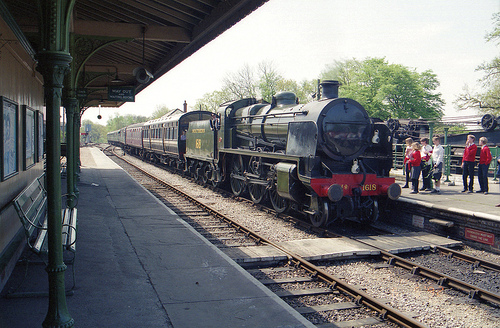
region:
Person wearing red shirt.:
[478, 141, 487, 176]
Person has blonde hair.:
[476, 128, 491, 155]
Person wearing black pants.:
[475, 163, 489, 184]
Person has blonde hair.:
[466, 130, 471, 141]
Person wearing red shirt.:
[462, 145, 472, 163]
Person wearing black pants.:
[461, 159, 473, 186]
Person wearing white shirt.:
[428, 140, 450, 169]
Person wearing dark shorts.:
[433, 160, 438, 175]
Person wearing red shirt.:
[404, 149, 419, 168]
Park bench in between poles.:
[18, 168, 80, 248]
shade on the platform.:
[119, 241, 144, 303]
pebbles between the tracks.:
[398, 278, 413, 306]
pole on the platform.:
[42, 275, 71, 320]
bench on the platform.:
[30, 192, 45, 243]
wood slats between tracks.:
[279, 276, 311, 296]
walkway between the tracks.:
[303, 240, 348, 270]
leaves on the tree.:
[392, 71, 415, 91]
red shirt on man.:
[462, 147, 475, 162]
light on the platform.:
[132, 65, 158, 90]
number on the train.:
[189, 135, 206, 152]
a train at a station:
[103, 79, 484, 266]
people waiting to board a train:
[397, 105, 497, 205]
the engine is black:
[214, 82, 403, 262]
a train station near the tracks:
[25, 37, 168, 290]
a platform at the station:
[59, 146, 186, 327]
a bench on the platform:
[4, 166, 103, 286]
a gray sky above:
[279, 12, 471, 79]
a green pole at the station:
[34, 11, 86, 308]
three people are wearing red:
[399, 124, 492, 206]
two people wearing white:
[415, 134, 465, 189]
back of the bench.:
[22, 191, 39, 223]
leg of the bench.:
[70, 251, 83, 281]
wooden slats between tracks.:
[287, 281, 322, 309]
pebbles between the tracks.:
[396, 289, 428, 310]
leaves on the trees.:
[387, 78, 427, 102]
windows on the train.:
[165, 129, 179, 137]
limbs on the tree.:
[242, 58, 251, 90]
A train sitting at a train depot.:
[18, 10, 493, 320]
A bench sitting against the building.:
[11, 173, 88, 269]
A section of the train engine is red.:
[280, 116, 401, 231]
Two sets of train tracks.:
[222, 223, 497, 325]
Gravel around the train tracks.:
[184, 159, 499, 326]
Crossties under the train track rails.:
[196, 208, 496, 321]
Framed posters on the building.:
[3, 84, 55, 184]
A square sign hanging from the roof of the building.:
[104, 79, 138, 106]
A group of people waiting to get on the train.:
[401, 126, 498, 201]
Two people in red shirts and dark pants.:
[457, 130, 496, 199]